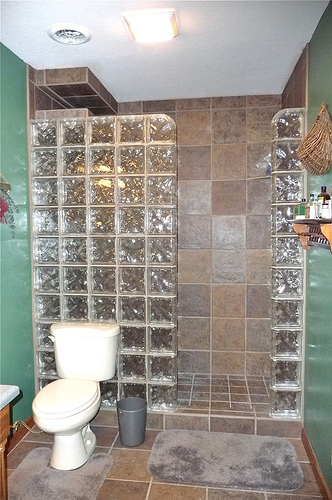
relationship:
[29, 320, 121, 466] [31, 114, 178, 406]
toilet in front of tile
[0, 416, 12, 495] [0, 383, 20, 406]
cabinet with counter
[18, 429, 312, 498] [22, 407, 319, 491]
rugs on floor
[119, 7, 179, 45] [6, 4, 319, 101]
light in ceiling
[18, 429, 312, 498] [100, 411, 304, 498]
rugs on floor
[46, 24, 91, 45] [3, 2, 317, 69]
vent on ceiling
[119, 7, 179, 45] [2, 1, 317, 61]
light on ceiling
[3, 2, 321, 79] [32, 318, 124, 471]
ceiling above toilet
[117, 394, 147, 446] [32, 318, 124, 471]
trashcan next to toilet